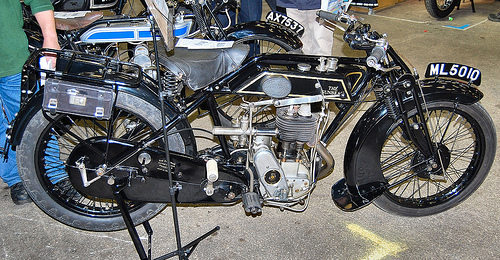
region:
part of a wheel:
[475, 108, 480, 120]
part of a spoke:
[386, 146, 406, 161]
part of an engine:
[288, 128, 299, 138]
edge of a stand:
[126, 225, 139, 239]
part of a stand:
[136, 216, 160, 224]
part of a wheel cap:
[376, 118, 389, 130]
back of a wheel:
[77, 203, 87, 229]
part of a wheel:
[346, 172, 357, 195]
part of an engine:
[281, 104, 301, 171]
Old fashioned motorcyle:
[6, 16, 498, 256]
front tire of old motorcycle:
[342, 80, 498, 220]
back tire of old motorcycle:
[15, 68, 188, 229]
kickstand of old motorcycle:
[103, 169, 160, 256]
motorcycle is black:
[2, 44, 492, 242]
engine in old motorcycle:
[217, 86, 337, 207]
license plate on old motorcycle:
[422, 55, 489, 82]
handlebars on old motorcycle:
[308, 5, 397, 81]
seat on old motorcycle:
[144, 30, 250, 101]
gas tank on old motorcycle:
[223, 55, 354, 105]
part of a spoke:
[456, 162, 472, 177]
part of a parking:
[321, 223, 335, 238]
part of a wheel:
[362, 135, 371, 163]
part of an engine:
[267, 160, 282, 174]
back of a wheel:
[100, 150, 112, 167]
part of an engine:
[261, 145, 276, 161]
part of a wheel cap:
[343, 202, 349, 227]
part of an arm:
[46, 35, 47, 47]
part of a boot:
[15, 193, 25, 200]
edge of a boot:
[21, 185, 29, 186]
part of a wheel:
[468, 183, 481, 191]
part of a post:
[352, 159, 362, 176]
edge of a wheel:
[159, 178, 181, 200]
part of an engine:
[271, 188, 286, 215]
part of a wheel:
[76, 143, 98, 159]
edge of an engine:
[291, 105, 317, 141]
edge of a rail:
[293, 123, 317, 146]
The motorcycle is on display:
[0, 10, 496, 246]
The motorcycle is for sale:
[0, 10, 496, 255]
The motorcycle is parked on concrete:
[0, 2, 488, 253]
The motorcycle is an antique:
[6, 23, 496, 255]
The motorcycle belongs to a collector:
[0, 13, 495, 243]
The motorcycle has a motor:
[5, 22, 475, 233]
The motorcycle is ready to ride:
[15, 8, 486, 244]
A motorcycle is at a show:
[5, 7, 497, 237]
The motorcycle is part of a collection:
[10, 30, 490, 230]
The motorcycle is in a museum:
[7, 20, 491, 235]